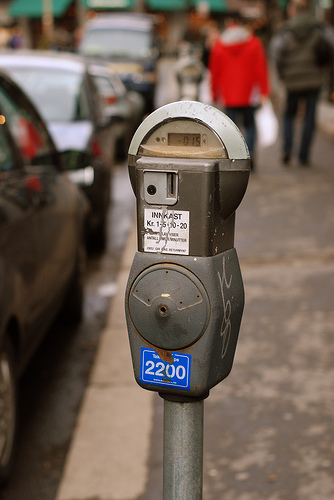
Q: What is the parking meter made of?
A: Metal.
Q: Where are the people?
A: On the sidewalk.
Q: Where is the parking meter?
A: On the metal pole.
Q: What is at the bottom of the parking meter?
A: A blue sticker.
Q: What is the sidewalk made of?
A: Cement.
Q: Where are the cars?
A: Parked on the road.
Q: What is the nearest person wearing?
A: A red coat.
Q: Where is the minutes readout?
A: Above the coin slot.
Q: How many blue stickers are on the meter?
A: One.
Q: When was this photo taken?
A: Daytime.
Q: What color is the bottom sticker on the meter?
A: Blue.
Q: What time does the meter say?
A: 15.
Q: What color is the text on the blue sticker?
A: White.